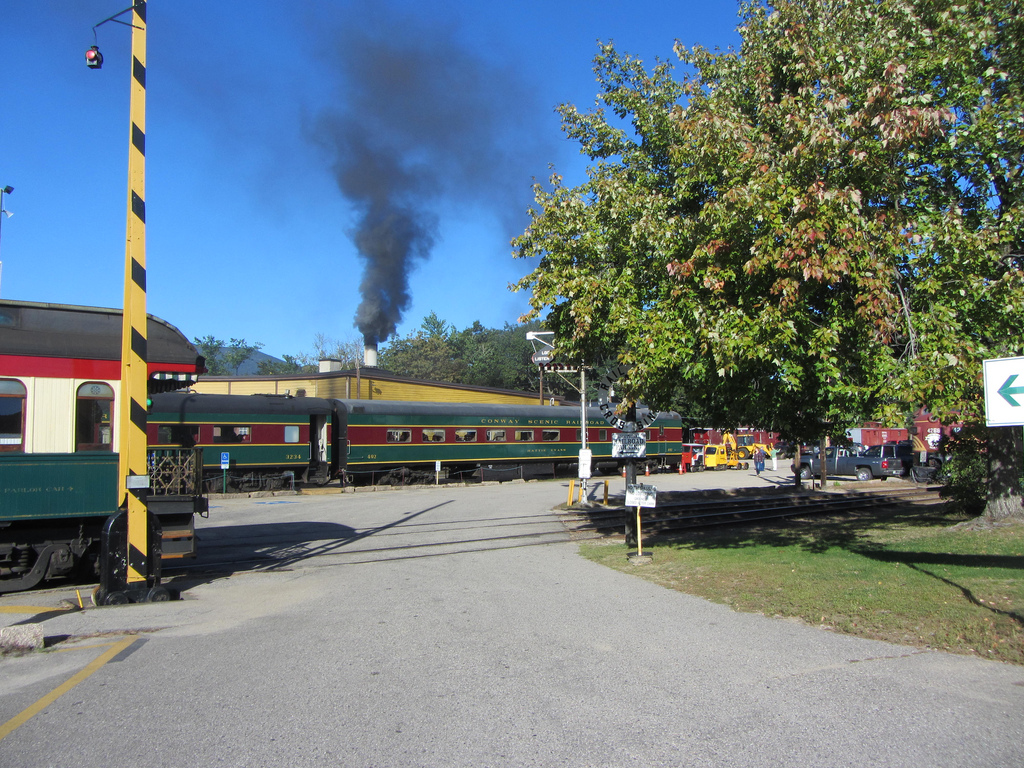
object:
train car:
[325, 397, 684, 487]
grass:
[556, 480, 1023, 666]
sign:
[982, 356, 1023, 427]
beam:
[93, 0, 170, 606]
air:
[0, 0, 1021, 766]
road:
[0, 457, 1024, 768]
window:
[212, 425, 252, 444]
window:
[386, 429, 412, 443]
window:
[421, 429, 477, 443]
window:
[454, 428, 478, 442]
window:
[485, 429, 534, 442]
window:
[515, 429, 535, 441]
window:
[542, 429, 561, 441]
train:
[0, 299, 709, 594]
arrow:
[997, 374, 1021, 406]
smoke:
[145, 9, 570, 349]